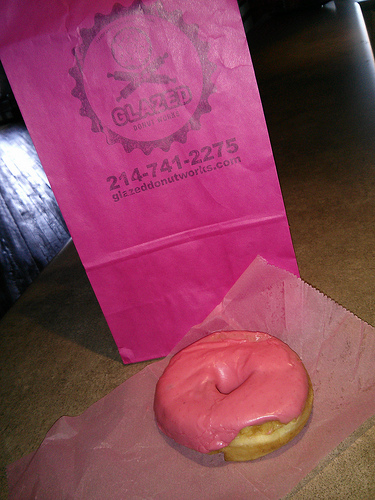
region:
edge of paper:
[346, 339, 357, 351]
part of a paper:
[145, 480, 156, 492]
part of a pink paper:
[114, 440, 121, 472]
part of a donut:
[247, 442, 251, 458]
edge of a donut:
[192, 417, 203, 443]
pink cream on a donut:
[202, 344, 206, 413]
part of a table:
[324, 206, 334, 221]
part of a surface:
[73, 357, 89, 394]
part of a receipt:
[170, 190, 181, 203]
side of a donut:
[337, 445, 340, 448]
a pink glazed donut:
[154, 337, 330, 467]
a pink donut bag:
[2, 3, 324, 261]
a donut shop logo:
[61, 3, 222, 150]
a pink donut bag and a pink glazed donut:
[6, 5, 363, 438]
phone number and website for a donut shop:
[88, 135, 268, 204]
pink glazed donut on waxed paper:
[3, 277, 367, 498]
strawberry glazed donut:
[154, 324, 317, 471]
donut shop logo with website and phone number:
[45, 4, 264, 208]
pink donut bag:
[6, 6, 368, 316]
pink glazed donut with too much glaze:
[150, 319, 323, 488]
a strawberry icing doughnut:
[154, 330, 315, 466]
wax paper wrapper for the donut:
[312, 290, 373, 457]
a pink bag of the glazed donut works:
[0, 0, 299, 269]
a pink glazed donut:
[155, 329, 313, 461]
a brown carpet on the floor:
[0, 313, 103, 398]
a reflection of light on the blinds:
[1, 129, 42, 305]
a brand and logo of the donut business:
[67, 0, 212, 151]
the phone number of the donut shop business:
[102, 135, 237, 187]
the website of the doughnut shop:
[108, 155, 257, 201]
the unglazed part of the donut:
[241, 428, 302, 460]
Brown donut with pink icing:
[153, 312, 317, 473]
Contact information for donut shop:
[98, 121, 261, 217]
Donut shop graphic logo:
[53, 5, 233, 156]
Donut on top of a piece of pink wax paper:
[28, 237, 364, 498]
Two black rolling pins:
[100, 62, 179, 101]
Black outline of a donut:
[101, 19, 152, 70]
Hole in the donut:
[204, 357, 257, 407]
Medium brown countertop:
[261, 11, 362, 293]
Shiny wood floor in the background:
[3, 109, 66, 322]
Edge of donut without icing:
[218, 409, 317, 467]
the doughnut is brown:
[142, 304, 332, 456]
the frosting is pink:
[150, 316, 325, 456]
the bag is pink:
[1, 1, 327, 367]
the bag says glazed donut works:
[92, 78, 226, 149]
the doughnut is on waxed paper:
[10, 258, 373, 498]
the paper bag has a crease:
[70, 165, 316, 295]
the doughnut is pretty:
[134, 314, 374, 468]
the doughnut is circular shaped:
[142, 303, 332, 464]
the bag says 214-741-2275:
[81, 126, 267, 229]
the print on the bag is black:
[42, 2, 263, 236]